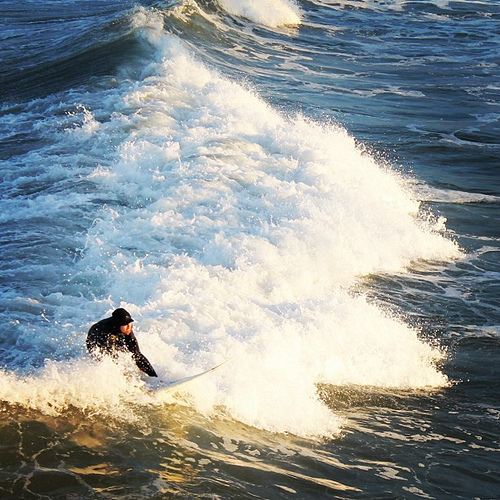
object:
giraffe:
[0, 39, 136, 105]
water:
[360, 53, 476, 93]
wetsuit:
[86, 317, 158, 378]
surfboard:
[125, 355, 234, 391]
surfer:
[86, 308, 159, 377]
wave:
[0, 0, 500, 452]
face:
[120, 322, 133, 335]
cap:
[112, 308, 134, 326]